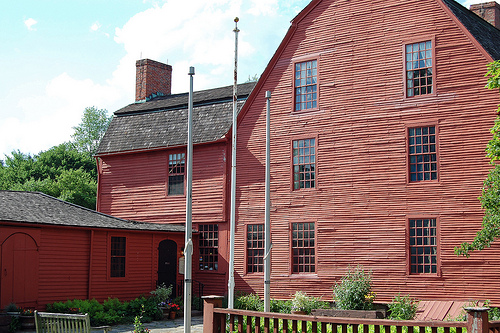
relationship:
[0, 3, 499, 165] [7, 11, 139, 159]
sky has some clouds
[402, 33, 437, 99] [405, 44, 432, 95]
window has curtains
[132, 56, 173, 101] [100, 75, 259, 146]
chimney sticking out of rooftop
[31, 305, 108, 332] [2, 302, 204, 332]
park bench on patio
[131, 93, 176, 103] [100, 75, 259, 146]
shadow cast on rooftop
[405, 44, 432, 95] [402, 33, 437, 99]
curtains on windows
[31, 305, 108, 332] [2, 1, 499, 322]
bench facing building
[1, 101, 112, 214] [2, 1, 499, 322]
trees behind building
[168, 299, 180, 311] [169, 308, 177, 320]
flower in pot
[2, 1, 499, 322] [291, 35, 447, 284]
building has windows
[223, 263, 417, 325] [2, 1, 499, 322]
bushes alongside building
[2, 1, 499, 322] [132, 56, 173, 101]
building has a chimney